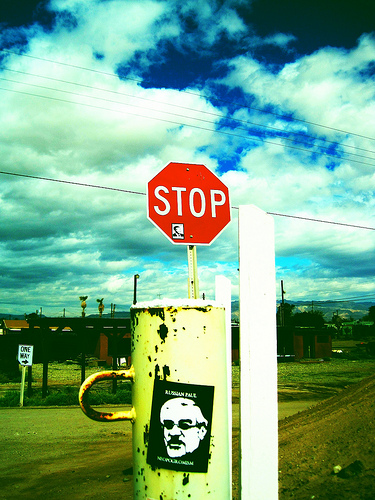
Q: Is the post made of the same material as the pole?
A: No, the post is made of concrete and the pole is made of metal.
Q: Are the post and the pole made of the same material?
A: No, the post is made of concrete and the pole is made of metal.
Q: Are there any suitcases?
A: No, there are no suitcases.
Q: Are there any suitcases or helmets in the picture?
A: No, there are no suitcases or helmets.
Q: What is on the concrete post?
A: The poster is on the post.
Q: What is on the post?
A: The poster is on the post.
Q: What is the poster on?
A: The poster is on the post.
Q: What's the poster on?
A: The poster is on the post.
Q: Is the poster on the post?
A: Yes, the poster is on the post.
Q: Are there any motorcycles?
A: No, there are no motorcycles.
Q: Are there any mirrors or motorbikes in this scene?
A: No, there are no motorbikes or mirrors.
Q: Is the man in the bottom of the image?
A: Yes, the man is in the bottom of the image.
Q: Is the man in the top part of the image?
A: No, the man is in the bottom of the image.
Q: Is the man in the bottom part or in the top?
A: The man is in the bottom of the image.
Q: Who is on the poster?
A: The man is on the poster.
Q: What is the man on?
A: The man is on the poster.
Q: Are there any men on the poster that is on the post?
A: Yes, there is a man on the poster.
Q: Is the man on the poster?
A: Yes, the man is on the poster.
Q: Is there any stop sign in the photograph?
A: Yes, there is a stop sign.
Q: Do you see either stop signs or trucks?
A: Yes, there is a stop sign.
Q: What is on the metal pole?
A: The stop sign is on the pole.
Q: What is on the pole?
A: The stop sign is on the pole.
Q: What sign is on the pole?
A: The sign is a stop sign.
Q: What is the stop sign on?
A: The stop sign is on the pole.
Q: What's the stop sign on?
A: The stop sign is on the pole.